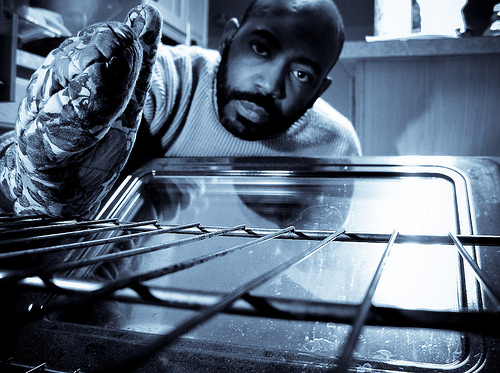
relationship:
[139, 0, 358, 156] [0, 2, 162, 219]
man wearing oven mitt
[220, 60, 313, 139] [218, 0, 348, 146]
beard on face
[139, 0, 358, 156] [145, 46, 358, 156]
man wearing sweater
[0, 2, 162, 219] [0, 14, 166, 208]
oven mitt on hand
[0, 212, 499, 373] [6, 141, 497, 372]
oven rack in oven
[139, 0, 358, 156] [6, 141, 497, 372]
man looking in oven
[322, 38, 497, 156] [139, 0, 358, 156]
cabinet behind man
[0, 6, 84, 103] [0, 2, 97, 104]
stuff on shelves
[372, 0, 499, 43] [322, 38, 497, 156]
window above cabinet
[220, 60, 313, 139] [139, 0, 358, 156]
beard on man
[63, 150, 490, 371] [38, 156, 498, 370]
window on oven door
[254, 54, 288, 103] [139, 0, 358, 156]
nose on man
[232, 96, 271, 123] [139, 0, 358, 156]
lips on man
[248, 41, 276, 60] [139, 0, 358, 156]
right eye on man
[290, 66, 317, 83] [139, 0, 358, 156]
left eye on man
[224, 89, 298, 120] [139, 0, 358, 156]
mustache on man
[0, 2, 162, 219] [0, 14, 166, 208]
oven mitt on right hand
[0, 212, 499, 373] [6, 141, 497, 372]
wire rack in oven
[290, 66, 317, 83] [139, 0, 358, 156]
left eye of man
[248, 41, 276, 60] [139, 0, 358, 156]
right eye of man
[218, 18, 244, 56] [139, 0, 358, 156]
right ear of man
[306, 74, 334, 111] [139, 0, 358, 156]
left ear of man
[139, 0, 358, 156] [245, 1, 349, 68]
man has bald head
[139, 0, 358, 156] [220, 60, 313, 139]
man has goatee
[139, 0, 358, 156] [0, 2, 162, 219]
man wears oven mitt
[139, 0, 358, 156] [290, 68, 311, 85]
man has left eye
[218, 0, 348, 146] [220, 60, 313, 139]
face has facial hair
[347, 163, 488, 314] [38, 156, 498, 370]
glare on oven door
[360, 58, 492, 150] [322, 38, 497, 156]
panel on cabinet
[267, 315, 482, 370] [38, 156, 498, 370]
marks on oven door